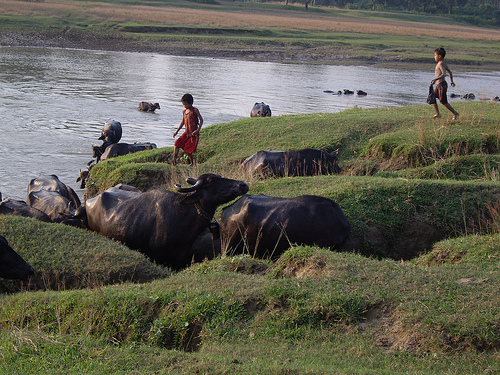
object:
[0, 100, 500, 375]
grass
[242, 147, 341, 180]
cow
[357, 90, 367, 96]
cow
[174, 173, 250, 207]
head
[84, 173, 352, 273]
cow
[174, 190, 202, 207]
ear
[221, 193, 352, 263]
hippo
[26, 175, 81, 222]
water buffalo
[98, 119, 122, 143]
water buffalo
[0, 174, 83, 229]
hippo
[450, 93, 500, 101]
cows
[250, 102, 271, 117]
cow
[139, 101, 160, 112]
cow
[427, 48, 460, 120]
boy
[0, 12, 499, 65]
grass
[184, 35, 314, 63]
dirt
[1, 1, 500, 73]
riverland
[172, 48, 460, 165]
children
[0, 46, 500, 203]
water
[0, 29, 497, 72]
bank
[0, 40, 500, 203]
lake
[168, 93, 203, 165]
boy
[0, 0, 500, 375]
ground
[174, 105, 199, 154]
clothing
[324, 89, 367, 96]
cows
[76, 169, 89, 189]
cows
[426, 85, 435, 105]
shirt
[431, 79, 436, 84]
hand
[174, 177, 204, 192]
horn